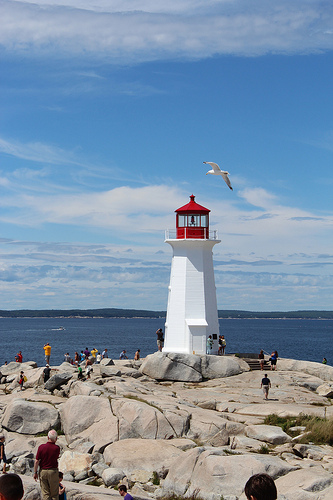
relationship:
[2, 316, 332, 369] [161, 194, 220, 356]
water past lighthouse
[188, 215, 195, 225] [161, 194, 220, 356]
light in lighthouse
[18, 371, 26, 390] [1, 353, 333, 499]
people on boulders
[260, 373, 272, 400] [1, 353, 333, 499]
man on boulders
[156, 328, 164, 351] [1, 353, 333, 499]
man on boulders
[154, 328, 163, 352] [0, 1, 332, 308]
man photographing sky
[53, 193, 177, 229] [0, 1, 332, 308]
clouds in sky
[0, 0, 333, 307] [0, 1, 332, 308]
clouds in sky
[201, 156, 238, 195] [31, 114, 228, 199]
bird in sky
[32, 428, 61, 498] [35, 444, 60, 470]
man with red shirt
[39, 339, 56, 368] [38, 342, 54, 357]
fat man with shirt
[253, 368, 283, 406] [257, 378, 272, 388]
man with shirt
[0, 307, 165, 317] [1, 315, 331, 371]
treeline of lake